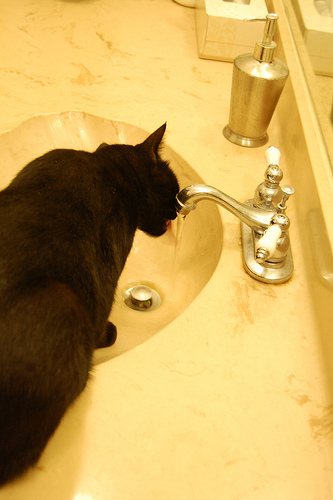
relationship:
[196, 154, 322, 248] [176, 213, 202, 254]
faucet has water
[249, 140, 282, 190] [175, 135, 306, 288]
handle for faucet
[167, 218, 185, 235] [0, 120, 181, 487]
tongue on cat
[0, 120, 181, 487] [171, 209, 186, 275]
cat drinking water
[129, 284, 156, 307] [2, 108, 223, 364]
plug in sink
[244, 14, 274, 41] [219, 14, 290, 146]
nozzle on dispenser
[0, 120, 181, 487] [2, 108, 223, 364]
cat in sink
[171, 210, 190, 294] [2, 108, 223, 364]
water in sink